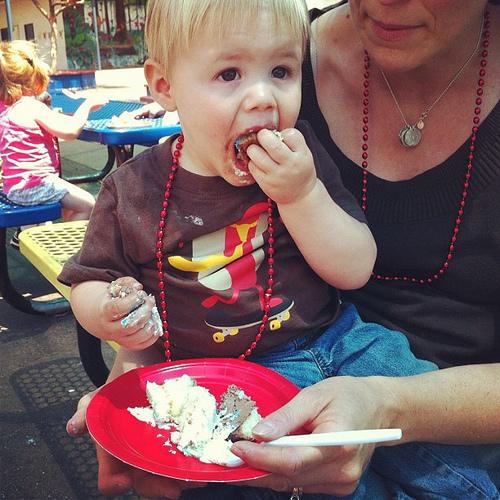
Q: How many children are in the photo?
A: Two.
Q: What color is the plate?
A: Red.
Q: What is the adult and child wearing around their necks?
A: Beads.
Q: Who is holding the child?
A: A lady.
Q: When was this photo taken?
A: During the daytime.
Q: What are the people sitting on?
A: Picnic tables.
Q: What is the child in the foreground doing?
A: Eating.